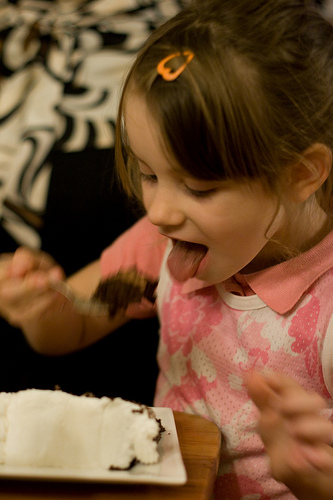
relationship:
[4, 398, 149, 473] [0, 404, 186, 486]
slice of cake on top of a plate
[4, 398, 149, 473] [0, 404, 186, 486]
slice of cake sitting on top of plate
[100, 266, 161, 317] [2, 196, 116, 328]
piece of cake on top of a fork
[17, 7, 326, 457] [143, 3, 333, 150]
girl has hair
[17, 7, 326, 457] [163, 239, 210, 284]
girl has a tongue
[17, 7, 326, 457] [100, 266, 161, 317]
girl eating piece of cake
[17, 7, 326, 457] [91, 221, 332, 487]
girl wearing a dress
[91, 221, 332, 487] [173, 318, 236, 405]
dress has patterns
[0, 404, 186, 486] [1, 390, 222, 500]
plate on top of a table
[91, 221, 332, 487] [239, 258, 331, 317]
dress has a collar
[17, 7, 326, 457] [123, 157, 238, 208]
girl has eyes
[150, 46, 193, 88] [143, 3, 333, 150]
barrett in hair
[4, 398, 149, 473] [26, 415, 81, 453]
slice of cake has icing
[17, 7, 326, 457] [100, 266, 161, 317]
girl eating a piece of cake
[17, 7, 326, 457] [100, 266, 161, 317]
girl enjoying eating a piece of cake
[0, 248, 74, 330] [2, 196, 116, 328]
hand holding fork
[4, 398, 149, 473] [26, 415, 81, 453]
slice of cake covered by icing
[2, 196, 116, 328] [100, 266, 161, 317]
fork holding piece of cake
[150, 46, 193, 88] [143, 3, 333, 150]
barrett inside hair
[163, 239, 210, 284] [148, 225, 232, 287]
tongue sticking out of a mouth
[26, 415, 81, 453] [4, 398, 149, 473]
icing on top of slice of cake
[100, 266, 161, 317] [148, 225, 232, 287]
piece of cake right next to mouth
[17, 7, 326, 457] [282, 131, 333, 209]
girl has an ear